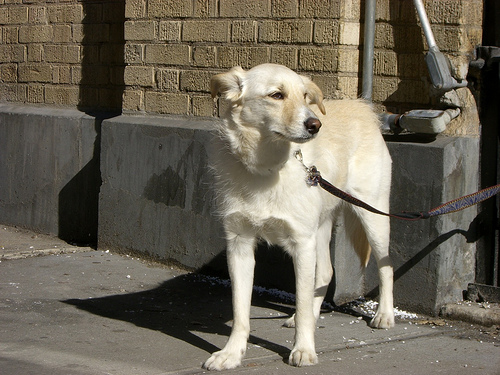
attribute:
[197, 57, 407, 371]
dog — standing, large, waiting, white, light colored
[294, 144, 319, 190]
clasp — metal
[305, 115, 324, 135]
nose — black, round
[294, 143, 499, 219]
leash — dark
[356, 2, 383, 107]
pole — metal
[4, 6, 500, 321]
building — brick, light colored, tan colored, tan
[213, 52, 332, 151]
head — sideways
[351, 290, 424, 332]
pellets — white